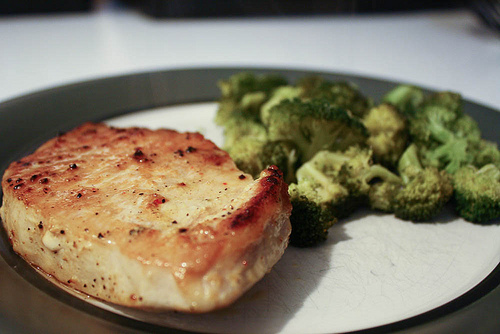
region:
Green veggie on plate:
[451, 158, 497, 215]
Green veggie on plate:
[397, 159, 442, 250]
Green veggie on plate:
[353, 152, 377, 214]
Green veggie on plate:
[290, 173, 350, 241]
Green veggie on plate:
[279, 101, 352, 152]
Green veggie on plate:
[210, 65, 265, 97]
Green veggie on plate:
[283, 72, 375, 119]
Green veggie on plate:
[364, 77, 461, 159]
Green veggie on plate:
[210, 83, 289, 173]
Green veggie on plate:
[279, 88, 345, 234]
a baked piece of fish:
[11, 100, 299, 316]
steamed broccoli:
[220, 67, 497, 237]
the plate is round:
[6, 74, 490, 326]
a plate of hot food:
[8, 77, 497, 318]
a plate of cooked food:
[3, 56, 489, 331]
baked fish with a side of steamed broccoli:
[1, 66, 493, 332]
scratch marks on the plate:
[261, 205, 466, 300]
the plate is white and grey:
[4, 75, 499, 330]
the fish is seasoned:
[4, 112, 345, 328]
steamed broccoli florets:
[223, 53, 497, 233]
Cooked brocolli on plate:
[217, 71, 497, 241]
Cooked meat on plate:
[2, 118, 296, 313]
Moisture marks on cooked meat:
[83, 216, 232, 275]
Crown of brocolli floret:
[269, 95, 371, 142]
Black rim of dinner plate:
[0, 64, 497, 326]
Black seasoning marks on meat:
[19, 152, 144, 305]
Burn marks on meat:
[226, 158, 283, 238]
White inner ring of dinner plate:
[12, 100, 495, 332]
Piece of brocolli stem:
[293, 153, 354, 200]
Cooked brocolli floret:
[397, 143, 449, 223]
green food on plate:
[282, 155, 333, 210]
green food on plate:
[294, 142, 333, 192]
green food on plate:
[351, 134, 385, 169]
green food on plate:
[385, 134, 445, 194]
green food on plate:
[426, 134, 476, 198]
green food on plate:
[380, 115, 417, 159]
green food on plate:
[329, 115, 374, 163]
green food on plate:
[295, 88, 342, 120]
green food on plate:
[371, 91, 404, 123]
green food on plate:
[299, 104, 341, 145]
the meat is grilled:
[18, 104, 273, 329]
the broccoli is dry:
[234, 79, 436, 226]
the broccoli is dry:
[189, 60, 498, 256]